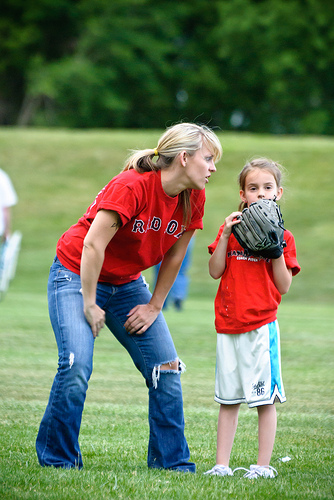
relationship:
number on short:
[252, 387, 265, 393] [213, 319, 291, 405]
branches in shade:
[26, 28, 316, 119] [171, 90, 275, 123]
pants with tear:
[38, 244, 211, 468] [155, 358, 182, 371]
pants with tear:
[38, 244, 211, 468] [67, 351, 74, 367]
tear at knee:
[155, 358, 182, 371] [156, 349, 183, 376]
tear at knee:
[67, 351, 74, 367] [67, 353, 92, 378]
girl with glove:
[203, 154, 301, 479] [232, 196, 285, 261]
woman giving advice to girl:
[34, 121, 223, 476] [203, 154, 301, 479]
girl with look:
[203, 154, 301, 479] [249, 173, 275, 202]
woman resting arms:
[34, 121, 223, 476] [74, 205, 200, 340]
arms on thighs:
[74, 205, 200, 340] [50, 260, 181, 367]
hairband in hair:
[152, 147, 158, 155] [126, 121, 219, 169]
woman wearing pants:
[34, 121, 223, 473] [32, 255, 198, 474]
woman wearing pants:
[34, 121, 223, 476] [46, 265, 183, 459]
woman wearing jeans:
[34, 121, 223, 473] [41, 259, 201, 473]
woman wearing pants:
[34, 121, 223, 476] [34, 250, 197, 473]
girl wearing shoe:
[207, 157, 296, 478] [243, 459, 274, 480]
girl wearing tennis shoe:
[207, 157, 296, 478] [202, 465, 234, 475]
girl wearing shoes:
[203, 154, 301, 479] [200, 461, 281, 486]